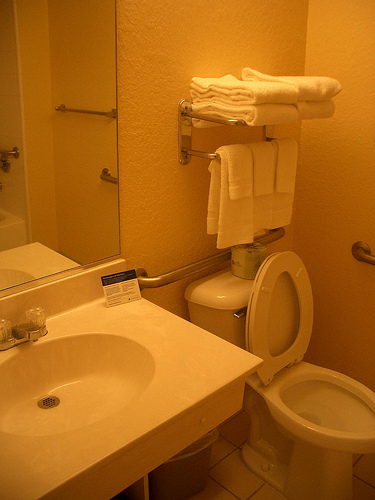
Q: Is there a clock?
A: No, there are no clocks.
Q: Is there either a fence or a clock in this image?
A: No, there are no clocks or fences.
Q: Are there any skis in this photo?
A: No, there are no skis.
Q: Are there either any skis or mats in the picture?
A: No, there are no skis or mats.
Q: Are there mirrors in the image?
A: Yes, there is a mirror.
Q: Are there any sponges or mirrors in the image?
A: Yes, there is a mirror.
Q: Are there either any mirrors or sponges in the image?
A: Yes, there is a mirror.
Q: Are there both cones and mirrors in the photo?
A: No, there is a mirror but no cones.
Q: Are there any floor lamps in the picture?
A: No, there are no floor lamps.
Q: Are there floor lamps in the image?
A: No, there are no floor lamps.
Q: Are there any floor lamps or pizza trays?
A: No, there are no floor lamps or pizza trays.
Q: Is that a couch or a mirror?
A: That is a mirror.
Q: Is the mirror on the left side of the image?
A: Yes, the mirror is on the left of the image.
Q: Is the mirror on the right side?
A: No, the mirror is on the left of the image.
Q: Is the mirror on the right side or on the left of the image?
A: The mirror is on the left of the image.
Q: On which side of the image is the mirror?
A: The mirror is on the left of the image.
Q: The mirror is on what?
A: The mirror is on the wall.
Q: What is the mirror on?
A: The mirror is on the wall.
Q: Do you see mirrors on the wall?
A: Yes, there is a mirror on the wall.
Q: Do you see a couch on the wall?
A: No, there is a mirror on the wall.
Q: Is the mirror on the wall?
A: Yes, the mirror is on the wall.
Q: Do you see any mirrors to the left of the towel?
A: Yes, there is a mirror to the left of the towel.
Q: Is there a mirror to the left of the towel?
A: Yes, there is a mirror to the left of the towel.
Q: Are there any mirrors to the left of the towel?
A: Yes, there is a mirror to the left of the towel.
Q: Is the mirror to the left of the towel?
A: Yes, the mirror is to the left of the towel.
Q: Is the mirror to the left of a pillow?
A: No, the mirror is to the left of the towel.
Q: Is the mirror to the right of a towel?
A: No, the mirror is to the left of a towel.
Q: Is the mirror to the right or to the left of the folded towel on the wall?
A: The mirror is to the left of the towel.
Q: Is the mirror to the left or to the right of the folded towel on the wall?
A: The mirror is to the left of the towel.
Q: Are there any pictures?
A: No, there are no pictures.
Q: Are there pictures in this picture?
A: No, there are no pictures.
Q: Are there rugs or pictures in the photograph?
A: No, there are no pictures or rugs.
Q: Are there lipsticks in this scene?
A: No, there are no lipsticks.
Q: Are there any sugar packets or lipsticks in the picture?
A: No, there are no lipsticks or sugar packets.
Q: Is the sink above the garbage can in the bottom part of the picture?
A: Yes, the sink is above the garbage can.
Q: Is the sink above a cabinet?
A: No, the sink is above the garbage can.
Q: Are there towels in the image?
A: Yes, there is a towel.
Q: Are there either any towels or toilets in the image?
A: Yes, there is a towel.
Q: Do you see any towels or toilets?
A: Yes, there is a towel.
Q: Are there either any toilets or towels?
A: Yes, there is a towel.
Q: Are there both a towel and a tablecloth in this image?
A: No, there is a towel but no tablecloths.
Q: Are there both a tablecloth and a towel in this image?
A: No, there is a towel but no tablecloths.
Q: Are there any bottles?
A: No, there are no bottles.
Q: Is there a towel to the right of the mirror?
A: Yes, there is a towel to the right of the mirror.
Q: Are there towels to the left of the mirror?
A: No, the towel is to the right of the mirror.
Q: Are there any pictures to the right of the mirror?
A: No, there is a towel to the right of the mirror.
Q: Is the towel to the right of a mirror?
A: Yes, the towel is to the right of a mirror.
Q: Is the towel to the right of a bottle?
A: No, the towel is to the right of a mirror.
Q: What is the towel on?
A: The towel is on the wall.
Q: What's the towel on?
A: The towel is on the wall.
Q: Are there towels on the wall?
A: Yes, there is a towel on the wall.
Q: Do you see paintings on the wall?
A: No, there is a towel on the wall.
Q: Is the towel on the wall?
A: Yes, the towel is on the wall.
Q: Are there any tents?
A: No, there are no tents.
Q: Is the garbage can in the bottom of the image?
A: Yes, the garbage can is in the bottom of the image.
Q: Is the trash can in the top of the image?
A: No, the trash can is in the bottom of the image.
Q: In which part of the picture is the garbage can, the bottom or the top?
A: The garbage can is in the bottom of the image.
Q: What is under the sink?
A: The garbage bin is under the sink.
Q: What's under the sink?
A: The garbage bin is under the sink.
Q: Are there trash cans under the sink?
A: Yes, there is a trash can under the sink.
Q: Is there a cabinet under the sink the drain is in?
A: No, there is a trash can under the sink.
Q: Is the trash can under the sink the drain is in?
A: Yes, the trash can is under the sink.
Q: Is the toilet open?
A: Yes, the toilet is open.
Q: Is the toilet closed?
A: No, the toilet is open.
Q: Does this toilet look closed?
A: No, the toilet is open.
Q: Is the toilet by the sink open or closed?
A: The toilet is open.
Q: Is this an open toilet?
A: Yes, this is an open toilet.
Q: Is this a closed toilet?
A: No, this is an open toilet.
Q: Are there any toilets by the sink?
A: Yes, there is a toilet by the sink.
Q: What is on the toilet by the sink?
A: The tissue paper is on the toilet.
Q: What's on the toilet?
A: The tissue paper is on the toilet.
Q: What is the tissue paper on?
A: The tissue paper is on the toilet.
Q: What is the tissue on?
A: The tissue paper is on the toilet.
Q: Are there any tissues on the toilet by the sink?
A: Yes, there is a tissue on the toilet.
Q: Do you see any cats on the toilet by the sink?
A: No, there is a tissue on the toilet.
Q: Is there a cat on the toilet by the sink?
A: No, there is a tissue on the toilet.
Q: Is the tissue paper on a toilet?
A: Yes, the tissue paper is on a toilet.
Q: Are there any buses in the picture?
A: No, there are no buses.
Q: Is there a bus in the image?
A: No, there are no buses.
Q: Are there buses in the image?
A: No, there are no buses.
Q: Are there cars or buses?
A: No, there are no buses or cars.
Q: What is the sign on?
A: The sign is on the counter.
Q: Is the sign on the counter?
A: Yes, the sign is on the counter.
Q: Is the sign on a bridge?
A: No, the sign is on the counter.